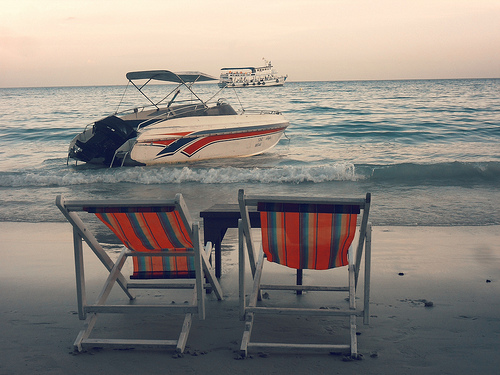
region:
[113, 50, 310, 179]
Two boat in the water.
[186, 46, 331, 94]
A boat in the water.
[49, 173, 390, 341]
Two beach chairs on the sand.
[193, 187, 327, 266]
Table in front of the chairs.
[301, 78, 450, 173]
The water is blue.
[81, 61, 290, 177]
The boat on the edge of the shoreline.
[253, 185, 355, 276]
The chair has stripes.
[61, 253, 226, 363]
The chair is made of iron.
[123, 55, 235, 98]
A canopy on the boat.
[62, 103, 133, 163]
The motor of the boat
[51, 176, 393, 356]
two chairs sitting on beach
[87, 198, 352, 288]
orange and blue fabric of chairs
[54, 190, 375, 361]
white frames of beach chairs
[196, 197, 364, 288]
black table in front of chairs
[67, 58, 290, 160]
boat closest to beach chairs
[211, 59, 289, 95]
boat out in the ocean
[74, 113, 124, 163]
black motor of boat closest to shore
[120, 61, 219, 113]
cover over boat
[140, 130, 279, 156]
blue and red stripes on side of boat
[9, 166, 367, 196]
white foam of wave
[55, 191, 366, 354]
Two chairs sitting on a beach.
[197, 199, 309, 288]
A blue table in front of the chairs.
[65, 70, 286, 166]
A boat sitting in the water.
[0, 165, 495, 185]
A wave rolling towards the shore.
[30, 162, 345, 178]
There is white water on the wave.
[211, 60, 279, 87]
There is a boat in the distance.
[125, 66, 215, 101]
The boat has a blue canopy.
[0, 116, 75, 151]
A wave is forming on the water.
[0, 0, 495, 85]
The sky is light pink.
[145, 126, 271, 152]
The boat has a red and a blue stripe.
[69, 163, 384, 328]
the chairs are striped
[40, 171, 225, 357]
chair's railings made of metal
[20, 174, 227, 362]
chair's railings are silver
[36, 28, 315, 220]
boat is in ocean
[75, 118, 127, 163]
boat has black engine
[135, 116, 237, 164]
red and blue lines on boat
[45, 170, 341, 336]
the chairs are empty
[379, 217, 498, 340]
the sand is wet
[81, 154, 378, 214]
waves sitting under boat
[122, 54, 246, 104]
boat has a canopy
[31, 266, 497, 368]
The sand on the beach is wet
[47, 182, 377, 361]
The chairs are sitting on the beach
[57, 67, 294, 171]
A boat sitting on the land and in the water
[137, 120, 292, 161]
The side of the boat is orange and blue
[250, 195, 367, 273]
The chair is blue and orange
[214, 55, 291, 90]
The boat is on the water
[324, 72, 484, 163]
The ocean water is calm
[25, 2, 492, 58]
The sky is gray and gloomy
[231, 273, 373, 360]
The leg's of the chair are white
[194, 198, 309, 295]
The table sitting in front of the chairs